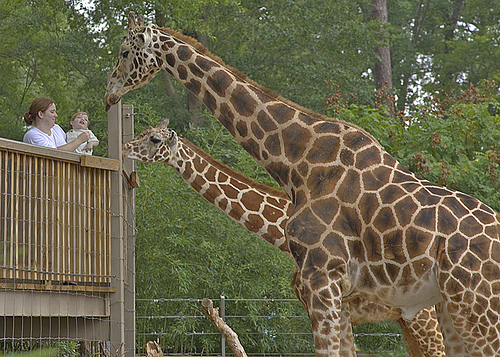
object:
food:
[96, 148, 111, 159]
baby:
[62, 109, 100, 157]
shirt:
[65, 127, 100, 155]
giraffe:
[100, 9, 499, 357]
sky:
[66, 0, 498, 133]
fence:
[133, 293, 403, 357]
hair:
[156, 24, 383, 148]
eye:
[120, 49, 128, 59]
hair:
[66, 110, 91, 123]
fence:
[0, 137, 118, 294]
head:
[102, 10, 164, 114]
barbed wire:
[139, 296, 298, 304]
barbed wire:
[134, 313, 304, 320]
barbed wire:
[135, 329, 403, 338]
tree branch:
[198, 297, 249, 356]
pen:
[0, 0, 499, 356]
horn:
[137, 11, 148, 26]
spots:
[303, 164, 344, 201]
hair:
[22, 97, 53, 128]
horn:
[123, 11, 139, 29]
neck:
[155, 26, 338, 203]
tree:
[0, 0, 498, 356]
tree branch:
[210, 4, 262, 52]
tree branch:
[393, 1, 433, 121]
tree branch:
[464, 2, 499, 33]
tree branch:
[40, 25, 96, 92]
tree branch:
[243, 46, 301, 80]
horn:
[156, 115, 172, 129]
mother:
[20, 95, 90, 155]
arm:
[30, 134, 87, 156]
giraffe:
[122, 116, 452, 356]